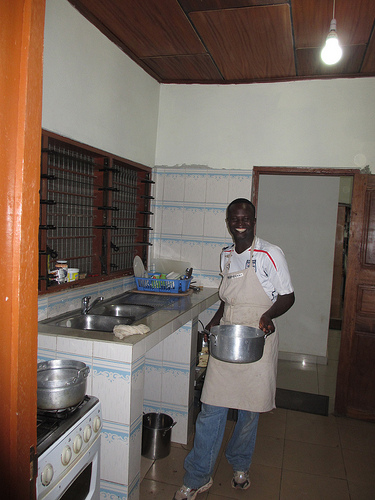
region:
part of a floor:
[278, 422, 313, 464]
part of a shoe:
[170, 476, 191, 498]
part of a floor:
[291, 437, 322, 473]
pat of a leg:
[180, 427, 212, 493]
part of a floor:
[264, 461, 279, 483]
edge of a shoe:
[229, 476, 248, 494]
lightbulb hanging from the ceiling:
[321, 18, 347, 73]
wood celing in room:
[194, 4, 294, 81]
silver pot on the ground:
[142, 413, 174, 458]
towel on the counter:
[111, 321, 152, 344]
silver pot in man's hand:
[203, 321, 265, 367]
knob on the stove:
[60, 442, 76, 469]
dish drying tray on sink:
[132, 274, 190, 290]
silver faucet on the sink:
[80, 296, 106, 313]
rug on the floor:
[277, 389, 332, 416]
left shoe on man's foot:
[229, 468, 253, 492]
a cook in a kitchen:
[75, 171, 327, 397]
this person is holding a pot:
[170, 185, 295, 427]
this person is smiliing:
[214, 194, 271, 257]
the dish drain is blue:
[119, 249, 200, 295]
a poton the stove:
[40, 356, 93, 412]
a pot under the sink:
[132, 403, 186, 458]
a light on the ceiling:
[308, 23, 351, 74]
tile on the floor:
[269, 402, 365, 498]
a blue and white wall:
[53, 340, 196, 493]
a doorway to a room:
[247, 159, 353, 409]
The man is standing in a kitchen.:
[42, 25, 363, 497]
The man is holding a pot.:
[201, 315, 270, 362]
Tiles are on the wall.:
[148, 162, 256, 286]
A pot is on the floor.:
[142, 405, 175, 459]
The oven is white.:
[32, 397, 103, 497]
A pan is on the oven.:
[35, 352, 85, 413]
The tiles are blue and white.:
[90, 339, 126, 493]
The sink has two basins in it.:
[42, 287, 151, 337]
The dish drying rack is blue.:
[129, 270, 192, 294]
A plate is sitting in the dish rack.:
[132, 252, 146, 276]